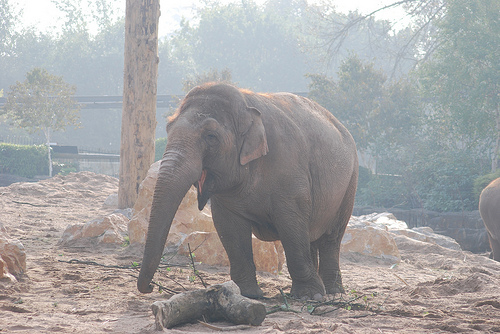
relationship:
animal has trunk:
[134, 79, 358, 302] [136, 144, 204, 294]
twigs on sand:
[308, 285, 387, 320] [7, 172, 497, 332]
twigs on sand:
[178, 234, 218, 289] [7, 172, 497, 332]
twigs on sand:
[128, 256, 184, 295] [7, 172, 497, 332]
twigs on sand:
[198, 308, 256, 328] [7, 172, 497, 332]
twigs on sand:
[67, 249, 142, 273] [7, 172, 497, 332]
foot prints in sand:
[58, 268, 93, 303] [7, 172, 497, 332]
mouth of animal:
[191, 147, 216, 209] [134, 79, 358, 302]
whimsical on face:
[191, 176, 266, 255] [155, 83, 246, 208]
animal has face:
[134, 79, 358, 302] [155, 83, 246, 208]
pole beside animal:
[118, 0, 160, 207] [134, 79, 358, 302]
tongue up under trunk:
[193, 168, 210, 193] [132, 143, 202, 298]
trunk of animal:
[132, 143, 202, 298] [134, 79, 358, 302]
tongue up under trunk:
[197, 168, 207, 193] [133, 147, 191, 294]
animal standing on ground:
[134, 79, 358, 302] [2, 172, 496, 329]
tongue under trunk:
[197, 168, 207, 193] [132, 143, 202, 298]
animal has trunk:
[134, 79, 358, 302] [132, 143, 202, 298]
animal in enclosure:
[134, 79, 358, 302] [0, 99, 497, 333]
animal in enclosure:
[123, 75, 361, 303] [2, 126, 483, 289]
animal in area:
[134, 79, 358, 302] [9, 166, 499, 332]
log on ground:
[144, 274, 268, 324] [2, 172, 496, 329]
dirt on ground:
[3, 171, 498, 331] [2, 172, 496, 329]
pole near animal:
[118, 0, 160, 207] [134, 79, 358, 302]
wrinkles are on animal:
[154, 144, 190, 175] [134, 79, 358, 302]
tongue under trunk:
[197, 168, 207, 193] [136, 144, 204, 294]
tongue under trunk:
[197, 168, 207, 193] [196, 170, 204, 197]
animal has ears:
[134, 79, 358, 302] [237, 103, 282, 166]